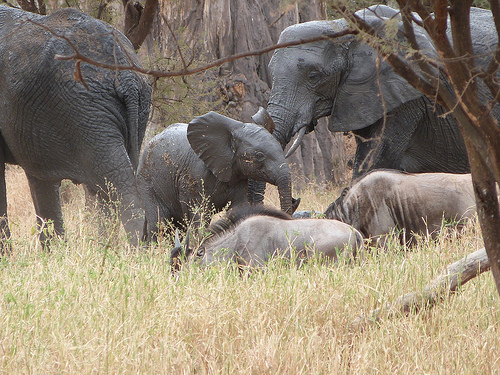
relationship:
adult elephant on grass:
[0, 1, 148, 253] [4, 163, 494, 373]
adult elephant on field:
[0, 1, 148, 253] [0, 132, 498, 372]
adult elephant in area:
[0, 1, 148, 253] [6, 13, 480, 368]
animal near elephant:
[163, 200, 365, 275] [1, 3, 151, 254]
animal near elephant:
[163, 200, 365, 275] [259, 1, 499, 185]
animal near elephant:
[321, 161, 481, 250] [1, 3, 151, 254]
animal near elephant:
[321, 161, 481, 250] [135, 106, 297, 242]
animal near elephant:
[321, 161, 481, 250] [259, 1, 499, 185]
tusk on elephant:
[284, 125, 306, 157] [245, 3, 497, 206]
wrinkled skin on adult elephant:
[9, 40, 152, 178] [0, 1, 148, 253]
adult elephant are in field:
[246, 3, 499, 207] [15, 171, 496, 372]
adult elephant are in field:
[0, 1, 148, 253] [17, 159, 490, 355]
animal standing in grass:
[327, 170, 480, 250] [3, 210, 496, 374]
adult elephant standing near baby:
[245, 3, 498, 201] [131, 111, 293, 236]